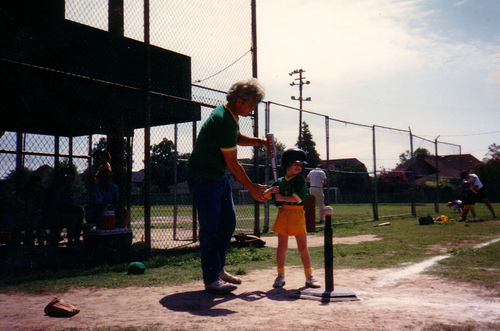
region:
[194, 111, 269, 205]
the shirt is green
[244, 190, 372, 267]
the skirt is yellow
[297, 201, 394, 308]
this is a tee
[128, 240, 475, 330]
this is home plate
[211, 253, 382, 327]
home plate is made of dirt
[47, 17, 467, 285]
this is a sporting game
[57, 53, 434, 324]
this is a tee ball game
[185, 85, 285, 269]
this is an adult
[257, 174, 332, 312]
this is a child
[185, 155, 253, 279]
the pants are blue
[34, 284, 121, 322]
the glove is in dirt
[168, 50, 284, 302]
this is a man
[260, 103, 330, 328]
this is a kid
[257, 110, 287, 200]
this is a bat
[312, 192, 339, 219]
this is a ball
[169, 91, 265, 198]
man wearing a green shirt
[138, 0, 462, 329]
kid is playing t ball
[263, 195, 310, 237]
kid wearing yellow shorts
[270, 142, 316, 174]
boy wearing a helmet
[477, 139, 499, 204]
a tree in a distance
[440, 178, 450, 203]
a tree in a distance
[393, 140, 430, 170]
a tree in a distance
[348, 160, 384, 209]
a tree in a distance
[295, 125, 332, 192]
a tree in a distance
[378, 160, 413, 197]
a tree in a distance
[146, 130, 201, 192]
a tree in a distance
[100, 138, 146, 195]
a tree in a distance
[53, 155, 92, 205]
a tree in a distance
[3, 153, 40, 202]
a tree in a distance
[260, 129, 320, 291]
child standing beside the tee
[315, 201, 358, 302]
tee with ball on it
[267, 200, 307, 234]
yellow shorts the batter is wearing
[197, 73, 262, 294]
man helping the batter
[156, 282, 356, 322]
shadows on the dirt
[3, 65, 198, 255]
players in a dugout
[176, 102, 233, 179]
green and yellow ringer shirt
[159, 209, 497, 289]
grass on the field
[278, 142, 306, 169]
helmet the batter is wearing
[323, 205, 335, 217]
ball on the tee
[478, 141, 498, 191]
a tree in a distance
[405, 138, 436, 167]
a tree in a distance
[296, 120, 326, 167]
a tree in a distance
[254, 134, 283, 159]
a tree in a distance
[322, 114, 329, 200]
metal pole on the chain link fence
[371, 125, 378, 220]
metal pole on the chain link fence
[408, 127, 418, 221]
metal pole on the chain link fence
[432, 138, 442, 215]
metal pole on the chain link fence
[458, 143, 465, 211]
metal pole on the chain link fence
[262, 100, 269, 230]
metal pole on the chain link fence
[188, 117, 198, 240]
metal pole on the chain link fence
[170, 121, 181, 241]
metal pole on the chain link fence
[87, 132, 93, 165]
metal pole on the chain link fence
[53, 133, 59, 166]
metal pole on the chain link fence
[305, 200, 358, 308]
A t-ball holder.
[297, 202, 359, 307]
A ball sitting on a holder.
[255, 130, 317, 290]
A child holding a baseball bat.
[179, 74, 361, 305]
An adult and child with a t-ball.